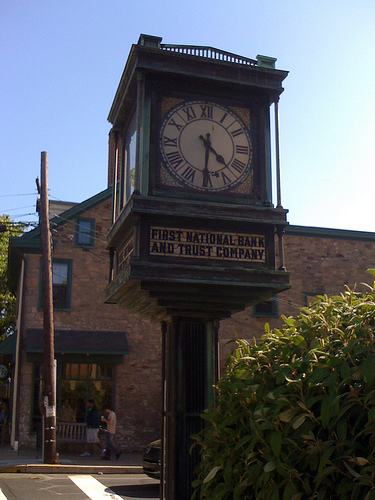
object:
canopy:
[25, 328, 130, 365]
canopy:
[0, 329, 18, 356]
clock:
[155, 85, 260, 200]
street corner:
[0, 480, 20, 500]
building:
[0, 182, 375, 455]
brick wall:
[18, 191, 375, 454]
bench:
[56, 422, 94, 455]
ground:
[0, 441, 161, 500]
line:
[67, 474, 124, 499]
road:
[0, 472, 164, 500]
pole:
[40, 151, 57, 465]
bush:
[189, 268, 375, 500]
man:
[100, 404, 122, 460]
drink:
[101, 415, 105, 419]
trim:
[48, 193, 108, 248]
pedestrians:
[79, 398, 107, 457]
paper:
[46, 406, 56, 417]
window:
[73, 214, 95, 249]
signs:
[149, 225, 266, 263]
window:
[30, 362, 43, 435]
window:
[59, 361, 116, 424]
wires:
[0, 204, 38, 214]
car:
[142, 435, 163, 481]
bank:
[237, 235, 265, 247]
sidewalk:
[0, 446, 144, 473]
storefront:
[29, 352, 117, 452]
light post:
[162, 313, 223, 500]